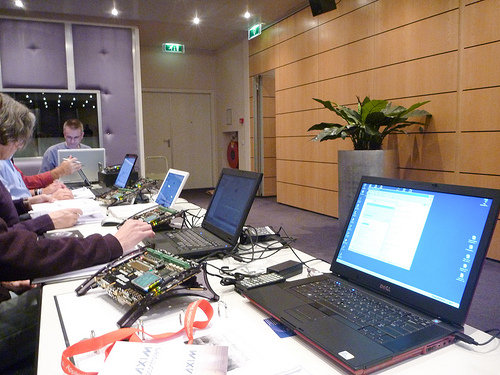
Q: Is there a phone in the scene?
A: No, there are no phones.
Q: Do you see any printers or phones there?
A: No, there are no phones or printers.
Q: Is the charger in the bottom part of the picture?
A: Yes, the charger is in the bottom of the image.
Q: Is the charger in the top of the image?
A: No, the charger is in the bottom of the image.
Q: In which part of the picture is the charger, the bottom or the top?
A: The charger is in the bottom of the image.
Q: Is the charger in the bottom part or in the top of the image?
A: The charger is in the bottom of the image.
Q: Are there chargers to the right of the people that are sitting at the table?
A: Yes, there is a charger to the right of the people.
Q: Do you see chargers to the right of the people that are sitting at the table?
A: Yes, there is a charger to the right of the people.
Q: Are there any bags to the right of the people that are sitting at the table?
A: No, there is a charger to the right of the people.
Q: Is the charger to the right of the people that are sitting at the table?
A: Yes, the charger is to the right of the people.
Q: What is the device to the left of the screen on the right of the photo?
A: The device is a charger.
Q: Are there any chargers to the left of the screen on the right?
A: Yes, there is a charger to the left of the screen.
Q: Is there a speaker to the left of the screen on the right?
A: No, there is a charger to the left of the screen.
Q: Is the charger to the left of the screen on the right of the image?
A: Yes, the charger is to the left of the screen.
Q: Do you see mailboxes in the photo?
A: No, there are no mailboxes.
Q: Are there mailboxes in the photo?
A: No, there are no mailboxes.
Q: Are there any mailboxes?
A: No, there are no mailboxes.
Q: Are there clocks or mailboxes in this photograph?
A: No, there are no mailboxes or clocks.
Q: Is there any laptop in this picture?
A: Yes, there is a laptop.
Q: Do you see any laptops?
A: Yes, there is a laptop.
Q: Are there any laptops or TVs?
A: Yes, there is a laptop.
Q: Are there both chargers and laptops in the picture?
A: Yes, there are both a laptop and a charger.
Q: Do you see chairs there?
A: No, there are no chairs.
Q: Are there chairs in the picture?
A: No, there are no chairs.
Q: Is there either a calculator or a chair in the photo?
A: No, there are no chairs or calculators.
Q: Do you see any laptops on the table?
A: Yes, there is a laptop on the table.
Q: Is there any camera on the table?
A: No, there is a laptop on the table.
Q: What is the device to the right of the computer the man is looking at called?
A: The device is a laptop.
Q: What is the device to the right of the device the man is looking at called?
A: The device is a laptop.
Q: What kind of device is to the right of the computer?
A: The device is a laptop.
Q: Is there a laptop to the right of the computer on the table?
A: Yes, there is a laptop to the right of the computer.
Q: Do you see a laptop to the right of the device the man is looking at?
A: Yes, there is a laptop to the right of the computer.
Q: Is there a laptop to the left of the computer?
A: No, the laptop is to the right of the computer.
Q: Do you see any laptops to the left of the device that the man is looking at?
A: No, the laptop is to the right of the computer.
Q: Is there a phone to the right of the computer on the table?
A: No, there is a laptop to the right of the computer.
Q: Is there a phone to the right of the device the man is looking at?
A: No, there is a laptop to the right of the computer.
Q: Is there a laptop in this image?
A: Yes, there is a laptop.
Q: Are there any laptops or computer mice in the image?
A: Yes, there is a laptop.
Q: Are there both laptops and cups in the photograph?
A: No, there is a laptop but no cups.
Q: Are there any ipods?
A: No, there are no ipods.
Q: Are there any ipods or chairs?
A: No, there are no ipods or chairs.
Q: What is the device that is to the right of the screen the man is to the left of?
A: The device is a laptop.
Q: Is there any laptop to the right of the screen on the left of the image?
A: Yes, there is a laptop to the right of the screen.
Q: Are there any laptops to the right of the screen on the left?
A: Yes, there is a laptop to the right of the screen.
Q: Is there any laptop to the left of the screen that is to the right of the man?
A: No, the laptop is to the right of the screen.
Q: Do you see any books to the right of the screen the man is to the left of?
A: No, there is a laptop to the right of the screen.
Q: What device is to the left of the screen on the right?
A: The device is a laptop.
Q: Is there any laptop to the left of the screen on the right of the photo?
A: Yes, there is a laptop to the left of the screen.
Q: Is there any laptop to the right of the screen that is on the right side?
A: No, the laptop is to the left of the screen.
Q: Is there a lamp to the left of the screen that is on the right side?
A: No, there is a laptop to the left of the screen.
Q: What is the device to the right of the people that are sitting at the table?
A: The device is a laptop.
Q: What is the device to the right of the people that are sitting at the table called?
A: The device is a laptop.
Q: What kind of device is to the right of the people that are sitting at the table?
A: The device is a laptop.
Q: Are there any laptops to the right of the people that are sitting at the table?
A: Yes, there is a laptop to the right of the people.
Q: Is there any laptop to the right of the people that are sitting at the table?
A: Yes, there is a laptop to the right of the people.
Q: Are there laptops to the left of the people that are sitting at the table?
A: No, the laptop is to the right of the people.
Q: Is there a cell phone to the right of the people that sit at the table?
A: No, there is a laptop to the right of the people.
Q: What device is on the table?
A: The device is a laptop.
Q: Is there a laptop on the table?
A: Yes, there is a laptop on the table.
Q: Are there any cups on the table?
A: No, there is a laptop on the table.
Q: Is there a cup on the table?
A: No, there is a laptop on the table.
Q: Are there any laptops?
A: Yes, there is a laptop.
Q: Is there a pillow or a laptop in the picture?
A: Yes, there is a laptop.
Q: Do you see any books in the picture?
A: No, there are no books.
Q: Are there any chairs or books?
A: No, there are no books or chairs.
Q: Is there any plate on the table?
A: No, there is a laptop on the table.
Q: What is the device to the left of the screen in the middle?
A: The device is a laptop.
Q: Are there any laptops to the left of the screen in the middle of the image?
A: Yes, there is a laptop to the left of the screen.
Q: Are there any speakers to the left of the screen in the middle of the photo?
A: No, there is a laptop to the left of the screen.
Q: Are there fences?
A: No, there are no fences.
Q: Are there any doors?
A: Yes, there is a door.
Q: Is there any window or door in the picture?
A: Yes, there is a door.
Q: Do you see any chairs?
A: No, there are no chairs.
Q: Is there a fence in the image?
A: No, there are no fences.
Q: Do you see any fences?
A: No, there are no fences.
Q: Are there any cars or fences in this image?
A: No, there are no fences or cars.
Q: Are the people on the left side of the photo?
A: Yes, the people are on the left of the image.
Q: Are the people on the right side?
A: No, the people are on the left of the image.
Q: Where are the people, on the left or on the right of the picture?
A: The people are on the left of the image.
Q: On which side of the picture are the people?
A: The people are on the left of the image.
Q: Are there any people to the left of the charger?
A: Yes, there are people to the left of the charger.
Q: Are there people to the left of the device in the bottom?
A: Yes, there are people to the left of the charger.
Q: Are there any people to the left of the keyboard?
A: Yes, there are people to the left of the keyboard.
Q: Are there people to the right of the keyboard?
A: No, the people are to the left of the keyboard.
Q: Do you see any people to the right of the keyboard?
A: No, the people are to the left of the keyboard.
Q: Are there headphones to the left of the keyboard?
A: No, there are people to the left of the keyboard.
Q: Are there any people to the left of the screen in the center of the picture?
A: Yes, there are people to the left of the screen.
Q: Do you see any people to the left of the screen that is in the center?
A: Yes, there are people to the left of the screen.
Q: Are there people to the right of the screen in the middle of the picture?
A: No, the people are to the left of the screen.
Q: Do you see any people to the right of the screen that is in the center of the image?
A: No, the people are to the left of the screen.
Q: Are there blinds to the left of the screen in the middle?
A: No, there are people to the left of the screen.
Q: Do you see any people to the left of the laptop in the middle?
A: Yes, there are people to the left of the laptop.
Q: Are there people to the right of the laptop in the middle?
A: No, the people are to the left of the laptop.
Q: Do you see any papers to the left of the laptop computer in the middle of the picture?
A: No, there are people to the left of the laptop.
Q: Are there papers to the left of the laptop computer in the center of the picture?
A: No, there are people to the left of the laptop.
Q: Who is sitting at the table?
A: The people are sitting at the table.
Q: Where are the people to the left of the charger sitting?
A: The people are sitting at the table.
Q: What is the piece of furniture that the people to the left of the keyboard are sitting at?
A: The piece of furniture is a table.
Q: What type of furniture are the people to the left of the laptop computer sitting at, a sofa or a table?
A: The people are sitting at a table.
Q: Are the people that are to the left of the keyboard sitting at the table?
A: Yes, the people are sitting at the table.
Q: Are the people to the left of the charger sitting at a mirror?
A: No, the people are sitting at the table.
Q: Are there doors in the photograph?
A: Yes, there is a door.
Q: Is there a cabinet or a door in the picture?
A: Yes, there is a door.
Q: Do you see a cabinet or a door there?
A: Yes, there is a door.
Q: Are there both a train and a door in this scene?
A: No, there is a door but no trains.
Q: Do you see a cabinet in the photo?
A: No, there are no cabinets.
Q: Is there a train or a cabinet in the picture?
A: No, there are no cabinets or trains.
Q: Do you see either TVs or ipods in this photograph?
A: No, there are no ipods or tvs.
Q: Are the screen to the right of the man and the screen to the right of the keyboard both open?
A: Yes, both the screen and the screen are open.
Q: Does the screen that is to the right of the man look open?
A: Yes, the screen is open.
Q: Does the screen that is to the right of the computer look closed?
A: No, the screen is open.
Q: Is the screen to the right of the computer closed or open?
A: The screen is open.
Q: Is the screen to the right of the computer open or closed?
A: The screen is open.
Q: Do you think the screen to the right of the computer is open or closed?
A: The screen is open.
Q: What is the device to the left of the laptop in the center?
A: The device is a screen.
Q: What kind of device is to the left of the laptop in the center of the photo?
A: The device is a screen.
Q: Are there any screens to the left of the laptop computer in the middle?
A: Yes, there is a screen to the left of the laptop.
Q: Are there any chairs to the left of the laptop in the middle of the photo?
A: No, there is a screen to the left of the laptop computer.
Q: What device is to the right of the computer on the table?
A: The device is a screen.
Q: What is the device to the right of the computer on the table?
A: The device is a screen.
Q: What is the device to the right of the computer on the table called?
A: The device is a screen.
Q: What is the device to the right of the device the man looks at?
A: The device is a screen.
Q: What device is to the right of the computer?
A: The device is a screen.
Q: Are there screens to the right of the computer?
A: Yes, there is a screen to the right of the computer.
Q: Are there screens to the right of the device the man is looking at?
A: Yes, there is a screen to the right of the computer.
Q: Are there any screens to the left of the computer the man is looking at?
A: No, the screen is to the right of the computer.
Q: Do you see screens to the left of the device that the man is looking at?
A: No, the screen is to the right of the computer.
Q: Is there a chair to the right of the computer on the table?
A: No, there is a screen to the right of the computer.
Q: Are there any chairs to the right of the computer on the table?
A: No, there is a screen to the right of the computer.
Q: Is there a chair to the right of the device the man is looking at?
A: No, there is a screen to the right of the computer.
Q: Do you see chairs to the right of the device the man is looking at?
A: No, there is a screen to the right of the computer.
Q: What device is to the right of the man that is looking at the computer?
A: The device is a screen.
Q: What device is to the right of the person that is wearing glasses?
A: The device is a screen.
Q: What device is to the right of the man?
A: The device is a screen.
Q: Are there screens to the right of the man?
A: Yes, there is a screen to the right of the man.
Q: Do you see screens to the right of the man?
A: Yes, there is a screen to the right of the man.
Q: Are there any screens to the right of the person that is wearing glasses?
A: Yes, there is a screen to the right of the man.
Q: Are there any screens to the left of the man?
A: No, the screen is to the right of the man.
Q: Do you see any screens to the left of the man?
A: No, the screen is to the right of the man.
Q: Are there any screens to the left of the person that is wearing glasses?
A: No, the screen is to the right of the man.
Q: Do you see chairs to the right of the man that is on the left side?
A: No, there is a screen to the right of the man.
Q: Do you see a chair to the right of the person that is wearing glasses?
A: No, there is a screen to the right of the man.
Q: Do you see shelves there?
A: No, there are no shelves.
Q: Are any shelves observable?
A: No, there are no shelves.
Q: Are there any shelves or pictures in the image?
A: No, there are no shelves or pictures.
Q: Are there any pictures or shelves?
A: No, there are no shelves or pictures.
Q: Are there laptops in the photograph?
A: Yes, there is a laptop.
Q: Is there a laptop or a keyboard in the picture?
A: Yes, there is a laptop.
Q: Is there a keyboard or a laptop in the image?
A: Yes, there is a laptop.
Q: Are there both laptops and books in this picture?
A: No, there is a laptop but no books.